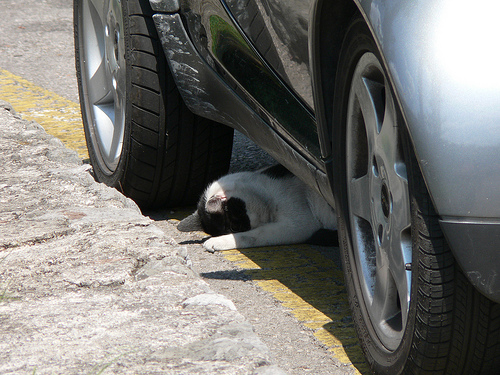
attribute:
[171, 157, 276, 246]
head — of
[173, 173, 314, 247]
cat — black, white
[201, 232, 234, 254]
paw — white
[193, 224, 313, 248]
leg — on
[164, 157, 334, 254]
cat — adult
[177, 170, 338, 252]
cat — adult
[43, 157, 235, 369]
curb — grey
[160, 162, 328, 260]
cat — white, black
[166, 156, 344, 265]
cat — white, black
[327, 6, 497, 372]
tires — black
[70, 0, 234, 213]
tires — black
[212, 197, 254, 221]
eye — closed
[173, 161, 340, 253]
cat — black, white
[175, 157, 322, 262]
cat — adult, black, under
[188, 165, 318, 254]
cat — under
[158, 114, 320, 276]
cat — black, bwhite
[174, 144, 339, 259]
cat — under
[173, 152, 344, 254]
feline — black, white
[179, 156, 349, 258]
cat — black, white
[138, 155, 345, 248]
cat — black, white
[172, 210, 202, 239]
ear — of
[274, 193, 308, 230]
white — on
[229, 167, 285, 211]
neck — on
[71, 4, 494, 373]
car — gray